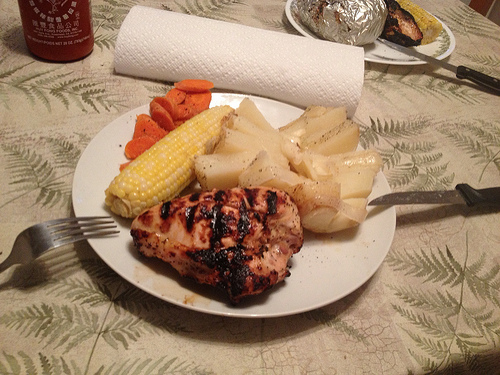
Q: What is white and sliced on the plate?
A: Potato.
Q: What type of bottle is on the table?
A: Sriracha.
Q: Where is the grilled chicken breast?
A: On the plate.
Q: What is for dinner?
A: Grilled chicken and vegetables.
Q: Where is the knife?
A: On the plate.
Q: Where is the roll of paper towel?
A: On the table.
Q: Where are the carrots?
A: On the plate.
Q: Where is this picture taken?
A: The kitchen.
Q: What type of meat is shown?
A: Chicken.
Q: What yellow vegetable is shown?
A: Corn.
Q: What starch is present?
A: Potatoes.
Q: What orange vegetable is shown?
A: Carrots.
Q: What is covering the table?
A: A tablecloth.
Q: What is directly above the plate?
A: Paper towels.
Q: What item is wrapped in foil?
A: A potato.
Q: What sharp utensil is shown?
A: A knife.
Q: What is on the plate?
A: Grilled chicken.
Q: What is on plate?
A: Corn on the cob.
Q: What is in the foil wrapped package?
A: Potato.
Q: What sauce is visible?
A: Sriracha.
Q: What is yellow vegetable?
A: Corn.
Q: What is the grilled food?
A: Chicken.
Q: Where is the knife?
A: Edge of plate.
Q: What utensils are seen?
A: Knife and fork.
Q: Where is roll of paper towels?
A: Between the plates.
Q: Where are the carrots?
A: Next to corn.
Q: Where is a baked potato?
A: Plate on far right.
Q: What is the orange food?
A: Carrots.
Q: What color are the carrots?
A: Orange.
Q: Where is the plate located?
A: On a table.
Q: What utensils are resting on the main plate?
A: Fork and knife.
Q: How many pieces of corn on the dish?
A: One.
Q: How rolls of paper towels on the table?
A: One.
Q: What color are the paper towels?
A: White.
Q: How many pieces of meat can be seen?
A: One.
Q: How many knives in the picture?
A: Two.